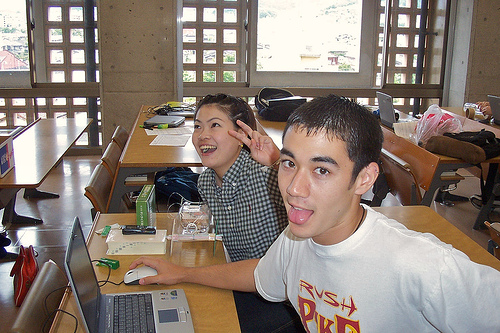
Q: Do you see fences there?
A: No, there are no fences.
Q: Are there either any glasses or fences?
A: No, there are no fences or glasses.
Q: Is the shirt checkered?
A: Yes, the shirt is checkered.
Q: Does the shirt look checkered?
A: Yes, the shirt is checkered.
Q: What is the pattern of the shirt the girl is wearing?
A: The shirt is checkered.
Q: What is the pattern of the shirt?
A: The shirt is checkered.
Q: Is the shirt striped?
A: No, the shirt is checkered.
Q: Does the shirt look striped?
A: No, the shirt is checkered.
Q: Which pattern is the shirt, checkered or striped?
A: The shirt is checkered.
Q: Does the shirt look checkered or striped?
A: The shirt is checkered.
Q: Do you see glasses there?
A: No, there are no glasses.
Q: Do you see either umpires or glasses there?
A: No, there are no glasses or umpires.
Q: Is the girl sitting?
A: Yes, the girl is sitting.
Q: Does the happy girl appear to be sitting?
A: Yes, the girl is sitting.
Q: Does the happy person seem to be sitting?
A: Yes, the girl is sitting.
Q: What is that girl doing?
A: The girl is sitting.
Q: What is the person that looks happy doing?
A: The girl is sitting.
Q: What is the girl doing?
A: The girl is sitting.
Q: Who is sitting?
A: The girl is sitting.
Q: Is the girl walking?
A: No, the girl is sitting.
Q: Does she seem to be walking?
A: No, the girl is sitting.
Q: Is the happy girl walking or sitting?
A: The girl is sitting.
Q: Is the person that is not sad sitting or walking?
A: The girl is sitting.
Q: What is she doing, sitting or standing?
A: The girl is sitting.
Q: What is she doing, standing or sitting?
A: The girl is sitting.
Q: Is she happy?
A: Yes, the girl is happy.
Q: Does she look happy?
A: Yes, the girl is happy.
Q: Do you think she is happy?
A: Yes, the girl is happy.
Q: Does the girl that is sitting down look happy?
A: Yes, the girl is happy.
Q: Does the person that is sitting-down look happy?
A: Yes, the girl is happy.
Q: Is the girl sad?
A: No, the girl is happy.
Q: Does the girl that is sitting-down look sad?
A: No, the girl is happy.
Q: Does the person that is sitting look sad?
A: No, the girl is happy.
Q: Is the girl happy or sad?
A: The girl is happy.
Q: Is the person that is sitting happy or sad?
A: The girl is happy.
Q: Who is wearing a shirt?
A: The girl is wearing a shirt.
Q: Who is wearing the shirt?
A: The girl is wearing a shirt.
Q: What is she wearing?
A: The girl is wearing a shirt.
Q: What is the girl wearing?
A: The girl is wearing a shirt.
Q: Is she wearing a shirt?
A: Yes, the girl is wearing a shirt.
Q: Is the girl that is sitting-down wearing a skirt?
A: No, the girl is wearing a shirt.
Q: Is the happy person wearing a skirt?
A: No, the girl is wearing a shirt.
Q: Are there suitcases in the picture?
A: No, there are no suitcases.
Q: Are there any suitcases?
A: No, there are no suitcases.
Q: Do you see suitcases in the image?
A: No, there are no suitcases.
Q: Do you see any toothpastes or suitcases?
A: No, there are no suitcases or toothpastes.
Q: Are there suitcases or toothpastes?
A: No, there are no suitcases or toothpastes.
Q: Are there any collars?
A: Yes, there is a collar.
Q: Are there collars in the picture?
A: Yes, there is a collar.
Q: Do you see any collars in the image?
A: Yes, there is a collar.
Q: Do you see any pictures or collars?
A: Yes, there is a collar.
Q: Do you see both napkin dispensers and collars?
A: No, there is a collar but no napkin dispensers.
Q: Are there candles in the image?
A: No, there are no candles.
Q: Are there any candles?
A: No, there are no candles.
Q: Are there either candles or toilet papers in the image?
A: No, there are no candles or toilet papers.